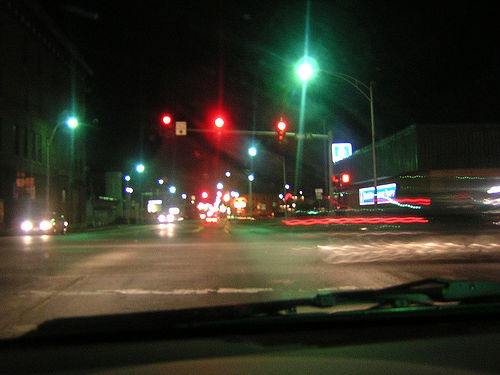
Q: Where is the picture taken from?
A: Inside a car.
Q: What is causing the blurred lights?
A: Fast movement.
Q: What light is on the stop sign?
A: Red light.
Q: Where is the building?
A: On the corner.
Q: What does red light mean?
A: Stop.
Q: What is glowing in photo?
A: Street lights.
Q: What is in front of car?
A: Intersection.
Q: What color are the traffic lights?
A: Red.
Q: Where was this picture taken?
A: Outside on street.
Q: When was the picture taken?
A: At night.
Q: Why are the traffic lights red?
A: To tell traffic to stop.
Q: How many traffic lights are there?
A: Three.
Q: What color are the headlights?
A: White.